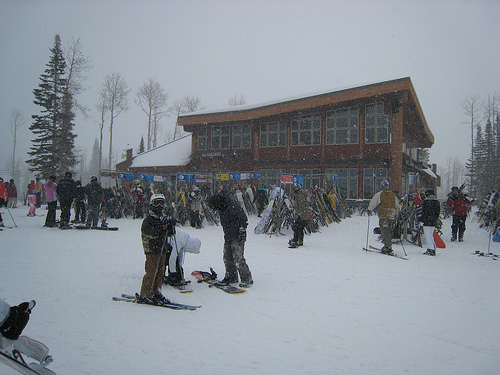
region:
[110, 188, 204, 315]
skier wearing brown ski pants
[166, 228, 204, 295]
person in white jacket bending over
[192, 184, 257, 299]
skier stepping on snowboard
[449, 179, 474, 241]
person carrying their skis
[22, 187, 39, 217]
child in pink snow gear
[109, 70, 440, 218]
ski lodge building with windows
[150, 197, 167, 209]
skiing safety googles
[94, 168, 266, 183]
advertising banners near ski rack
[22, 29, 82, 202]
tallest pine tree in area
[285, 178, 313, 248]
person riding a snowboard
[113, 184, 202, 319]
a boy on some skiis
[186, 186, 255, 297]
a person strapping into a snowboard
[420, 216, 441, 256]
white snowboarding pants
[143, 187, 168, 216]
a white helmet on a boy's head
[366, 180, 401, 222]
a brown and white jacket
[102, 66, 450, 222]
a brown skii lodge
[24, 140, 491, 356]
a group of people snowboarding and skiing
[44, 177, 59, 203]
a pink and white jacket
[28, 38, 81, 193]
a large evergreen tree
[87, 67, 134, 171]
a large barren tree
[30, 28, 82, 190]
tall ever green tree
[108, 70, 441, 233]
brown wooden ski lodge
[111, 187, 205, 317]
person on a pair of skis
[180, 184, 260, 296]
person getting on a snow board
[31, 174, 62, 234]
person wearing a pink ski jacket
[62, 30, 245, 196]
row of tall leafless trees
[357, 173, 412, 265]
person wearing a brown jacket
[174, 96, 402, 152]
row of large angular windows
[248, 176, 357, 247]
pile of skis and snow boards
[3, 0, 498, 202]
hazy gray snowy sky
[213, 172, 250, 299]
person is on a snowboard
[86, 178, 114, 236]
person is on a snowboard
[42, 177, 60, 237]
person is on a snowboard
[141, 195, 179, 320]
person is on skis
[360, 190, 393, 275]
person is on skis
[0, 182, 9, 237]
person is on skis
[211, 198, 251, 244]
person is wearing a snow jacket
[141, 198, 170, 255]
person is wearing a snow jacket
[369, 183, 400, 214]
person is wearing a snow jacket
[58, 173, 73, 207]
person is wearing a snow jacket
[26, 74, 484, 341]
people at a ski resort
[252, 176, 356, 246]
there are racks of snowboards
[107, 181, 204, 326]
he is on skis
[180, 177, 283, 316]
he is looking to put on the snowboard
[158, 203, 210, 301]
he is fastening his boot on the snowboard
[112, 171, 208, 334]
he is wearing a white helmet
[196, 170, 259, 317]
he is wearing a black jacket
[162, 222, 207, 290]
he is wearing a white jacket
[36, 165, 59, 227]
she is wearing a pink jacket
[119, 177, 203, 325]
his ski poles are blue